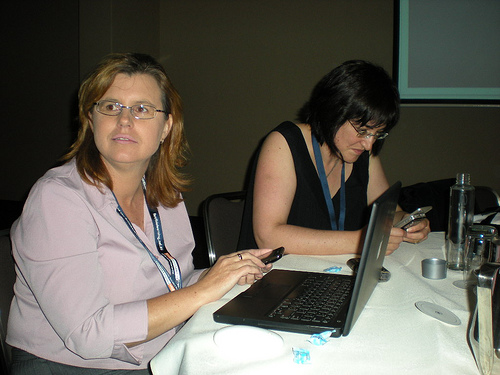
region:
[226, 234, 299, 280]
this is a cell phone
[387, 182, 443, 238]
this is a slider phone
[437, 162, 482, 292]
a glass bottle of water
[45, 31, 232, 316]
she has brown hair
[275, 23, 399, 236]
she has black hair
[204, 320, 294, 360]
this is a computer mouse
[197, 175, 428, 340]
this is a black laptop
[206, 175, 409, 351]
this is a black MacBook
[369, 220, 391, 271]
this is the Apple logo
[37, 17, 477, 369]
they are both wearing blue lanyards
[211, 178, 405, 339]
A black colored laptop.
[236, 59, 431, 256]
A woman wearing black.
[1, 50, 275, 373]
A woman in a pink shirt.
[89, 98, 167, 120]
A pair of glasses.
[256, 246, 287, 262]
A black colored cell phone.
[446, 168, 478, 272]
A clear drinking bottle.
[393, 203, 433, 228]
A silver cell phone.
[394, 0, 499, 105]
A white framed board.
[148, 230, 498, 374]
A white colored tablecloth.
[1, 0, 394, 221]
A tan colored wall.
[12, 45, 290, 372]
a woman using her phone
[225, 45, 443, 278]
a woman using her phone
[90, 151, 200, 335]
a blue, white, and orange lanyard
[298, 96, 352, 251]
a blue lanyard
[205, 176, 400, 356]
a black dell laptop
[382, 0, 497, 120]
a black and white projector screen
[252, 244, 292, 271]
a black cellphone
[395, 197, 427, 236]
a silver cellphone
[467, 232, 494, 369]
a silver water pitchet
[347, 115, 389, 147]
a pair of glasses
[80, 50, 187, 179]
woman wearing pair of glasses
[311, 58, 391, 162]
woman wearing pair of glasses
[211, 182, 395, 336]
black laptop sitting on top of table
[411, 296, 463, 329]
white disk sitting on table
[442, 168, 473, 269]
bottle of water sitting on table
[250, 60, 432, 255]
woman holding cellphone in hands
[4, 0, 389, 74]
dark wall behind women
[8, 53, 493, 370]
two women sitting at table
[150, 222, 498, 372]
table covered with white tabletop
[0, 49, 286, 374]
Woman is wearing glasses.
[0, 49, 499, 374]
Two women are sitting at a table.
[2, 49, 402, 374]
Woman holding cellphone is sitting in front of black lap top.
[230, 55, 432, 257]
Woman in black shirt is looking at her cellphone.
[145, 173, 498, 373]
Table with white tablecloth has laptop on it.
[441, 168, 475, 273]
Clear glass bottle is empty.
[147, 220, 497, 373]
White CD is lying on table.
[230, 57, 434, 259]
Woman is wearing a black top.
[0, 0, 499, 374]
Women are sitting at table in room with tan walls.